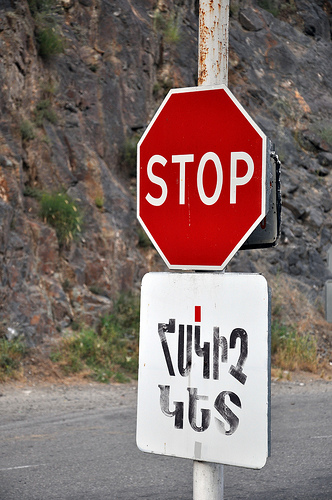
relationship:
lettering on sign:
[156, 316, 248, 383] [134, 272, 271, 470]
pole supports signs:
[191, 0, 230, 499] [136, 85, 274, 469]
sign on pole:
[132, 87, 261, 267] [191, 0, 230, 499]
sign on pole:
[136, 84, 267, 271] [181, 0, 241, 497]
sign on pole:
[134, 272, 271, 470] [181, 0, 241, 497]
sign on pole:
[136, 84, 267, 271] [191, 0, 230, 499]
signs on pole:
[136, 85, 274, 469] [191, 0, 230, 499]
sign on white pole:
[136, 84, 267, 271] [193, 460, 223, 498]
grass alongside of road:
[93, 315, 134, 363] [7, 383, 302, 498]